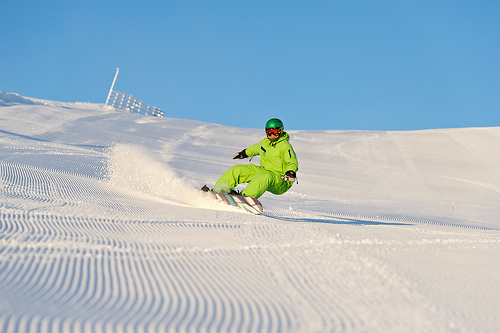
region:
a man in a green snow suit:
[203, 118, 304, 206]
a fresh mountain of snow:
[0, 206, 302, 331]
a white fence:
[101, 69, 167, 116]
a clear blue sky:
[88, 0, 497, 113]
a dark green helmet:
[263, 117, 285, 139]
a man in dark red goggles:
[265, 117, 287, 141]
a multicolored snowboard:
[196, 190, 263, 217]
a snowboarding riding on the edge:
[191, 116, 296, 216]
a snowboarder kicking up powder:
[108, 113, 298, 220]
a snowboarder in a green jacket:
[197, 119, 302, 211]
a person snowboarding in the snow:
[183, 97, 305, 228]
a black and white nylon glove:
[281, 165, 296, 181]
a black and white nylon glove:
[231, 149, 245, 161]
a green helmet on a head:
[264, 119, 280, 127]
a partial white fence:
[106, 82, 161, 115]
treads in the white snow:
[55, 247, 190, 319]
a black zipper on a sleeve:
[286, 146, 293, 158]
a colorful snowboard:
[216, 192, 259, 208]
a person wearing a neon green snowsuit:
[199, 114, 310, 217]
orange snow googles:
[264, 127, 281, 137]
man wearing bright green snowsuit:
[206, 113, 300, 223]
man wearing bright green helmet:
[263, 115, 288, 147]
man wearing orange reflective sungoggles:
[263, 116, 285, 143]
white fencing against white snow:
[103, 63, 170, 120]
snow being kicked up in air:
[102, 138, 203, 203]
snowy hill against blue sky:
[315, 58, 489, 205]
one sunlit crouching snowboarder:
[185, 112, 306, 232]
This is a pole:
[98, 55, 123, 117]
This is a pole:
[124, 87, 134, 119]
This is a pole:
[131, 93, 138, 118]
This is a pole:
[134, 96, 146, 119]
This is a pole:
[144, 98, 153, 115]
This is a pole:
[149, 102, 159, 116]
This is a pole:
[155, 104, 162, 121]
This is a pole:
[159, 106, 168, 122]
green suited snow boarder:
[199, 99, 304, 229]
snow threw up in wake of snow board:
[94, 136, 208, 216]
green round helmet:
[263, 105, 295, 152]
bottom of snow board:
[198, 184, 261, 219]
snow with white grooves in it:
[63, 195, 221, 298]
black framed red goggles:
[264, 127, 280, 136]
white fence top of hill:
[97, 73, 169, 128]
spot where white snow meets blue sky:
[370, 114, 496, 140]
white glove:
[276, 166, 301, 186]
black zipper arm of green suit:
[285, 145, 297, 163]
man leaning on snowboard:
[197, 111, 301, 202]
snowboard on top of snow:
[195, 182, 267, 217]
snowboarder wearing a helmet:
[261, 115, 283, 136]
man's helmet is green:
[261, 111, 282, 130]